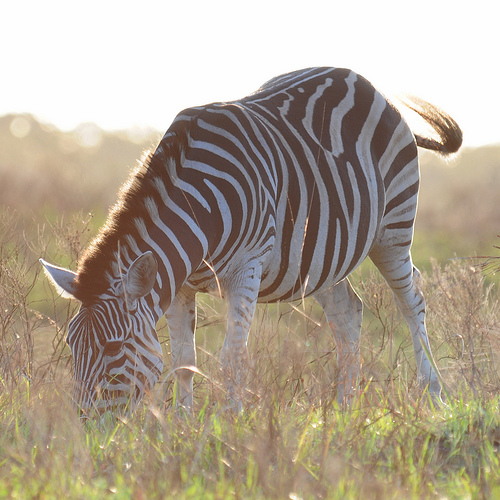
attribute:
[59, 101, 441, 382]
zebra — black, white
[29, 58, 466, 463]
zebra — grazing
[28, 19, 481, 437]
zebra — striped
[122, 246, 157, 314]
ear — large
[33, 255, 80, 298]
ear — large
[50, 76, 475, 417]
zebra — grazing, striped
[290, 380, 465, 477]
grass — long, wavy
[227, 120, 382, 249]
stripes — black, white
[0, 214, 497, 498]
grass — green, brown, green and brown 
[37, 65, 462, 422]
zebra — striped, black, white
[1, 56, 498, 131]
bright sky — grey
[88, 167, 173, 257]
mane — white, black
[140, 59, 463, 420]
zebra — striped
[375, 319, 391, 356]
stems — long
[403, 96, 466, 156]
tail — black